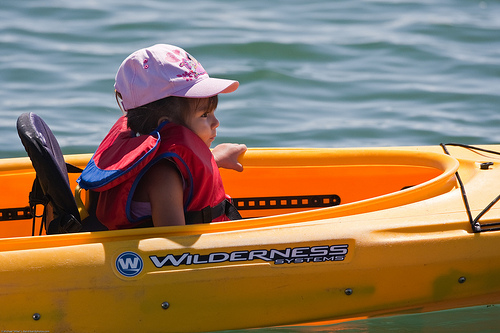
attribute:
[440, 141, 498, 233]
rope — black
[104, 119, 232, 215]
vest — blue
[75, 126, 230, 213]
life jacket — blue, red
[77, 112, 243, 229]
life jacket — red, blue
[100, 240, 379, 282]
lettering — black, white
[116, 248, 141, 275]
logo — black, blue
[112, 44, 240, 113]
cap — pink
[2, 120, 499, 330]
kayak — yellow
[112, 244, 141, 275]
logo — blue, white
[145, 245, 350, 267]
writing — black, white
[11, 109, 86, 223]
back — blue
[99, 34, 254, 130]
hat — pink